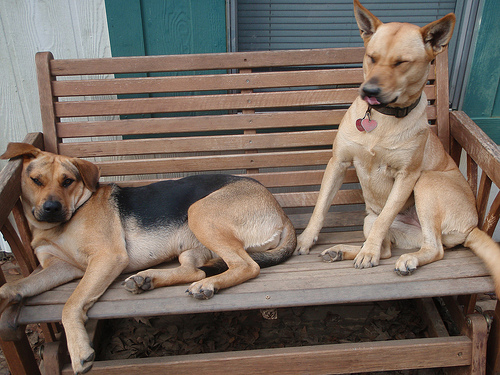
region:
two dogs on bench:
[38, 35, 435, 332]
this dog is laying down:
[9, 77, 291, 364]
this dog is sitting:
[311, 0, 488, 289]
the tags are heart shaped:
[352, 105, 399, 140]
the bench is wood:
[31, 37, 488, 279]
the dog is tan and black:
[1, 122, 296, 308]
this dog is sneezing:
[337, 5, 469, 299]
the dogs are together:
[21, 20, 481, 297]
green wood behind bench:
[103, 12, 294, 127]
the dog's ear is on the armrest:
[7, 120, 128, 243]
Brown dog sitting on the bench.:
[295, 0, 499, 294]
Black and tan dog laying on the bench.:
[0, 138, 299, 372]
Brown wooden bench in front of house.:
[0, 41, 498, 371]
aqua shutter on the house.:
[101, 1, 231, 158]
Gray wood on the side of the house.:
[0, 3, 155, 178]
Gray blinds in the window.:
[237, 2, 477, 114]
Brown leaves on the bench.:
[107, 295, 455, 366]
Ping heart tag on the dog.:
[360, 113, 375, 133]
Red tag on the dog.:
[355, 115, 362, 130]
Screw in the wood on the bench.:
[457, 348, 467, 357]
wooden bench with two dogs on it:
[0, 45, 498, 374]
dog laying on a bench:
[0, 140, 297, 373]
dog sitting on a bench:
[296, 0, 499, 299]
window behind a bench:
[236, 0, 456, 51]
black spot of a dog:
[112, 173, 257, 227]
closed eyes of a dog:
[365, 53, 407, 66]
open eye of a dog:
[61, 178, 73, 185]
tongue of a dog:
[363, 95, 378, 105]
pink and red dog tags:
[356, 118, 378, 133]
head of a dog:
[0, 141, 101, 224]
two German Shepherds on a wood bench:
[0, 14, 499, 374]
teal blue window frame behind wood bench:
[103, 12, 498, 142]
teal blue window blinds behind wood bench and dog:
[228, 17, 477, 136]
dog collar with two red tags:
[353, 94, 420, 133]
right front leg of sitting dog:
[294, 157, 349, 256]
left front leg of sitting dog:
[353, 170, 416, 267]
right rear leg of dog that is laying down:
[117, 250, 209, 294]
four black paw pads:
[124, 274, 154, 294]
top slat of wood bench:
[52, 41, 440, 76]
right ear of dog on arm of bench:
[0, 129, 41, 212]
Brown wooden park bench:
[34, 46, 271, 129]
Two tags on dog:
[326, 99, 403, 132]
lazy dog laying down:
[3, 140, 293, 335]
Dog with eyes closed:
[317, 0, 488, 283]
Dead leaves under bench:
[146, 328, 401, 345]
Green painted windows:
[116, 8, 226, 53]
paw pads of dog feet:
[130, 271, 160, 294]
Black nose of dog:
[36, 192, 76, 229]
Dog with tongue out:
[362, 95, 386, 115]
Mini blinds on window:
[258, 7, 334, 42]